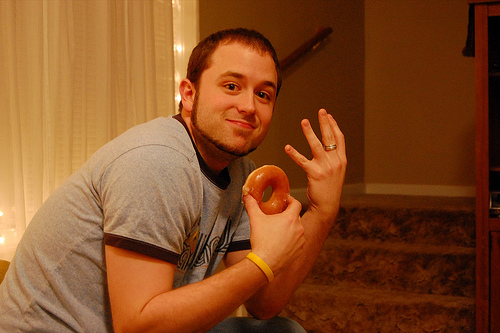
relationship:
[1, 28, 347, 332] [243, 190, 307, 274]
man has hand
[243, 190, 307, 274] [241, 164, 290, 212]
hand holding donut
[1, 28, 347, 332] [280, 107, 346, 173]
man holding up fingers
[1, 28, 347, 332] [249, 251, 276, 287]
man has wrist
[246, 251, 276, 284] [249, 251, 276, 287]
band around wrist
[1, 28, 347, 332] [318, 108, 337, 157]
man has finger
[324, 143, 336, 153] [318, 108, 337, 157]
ring around finger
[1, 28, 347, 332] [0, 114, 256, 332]
man wearing shirt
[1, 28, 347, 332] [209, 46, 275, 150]
man has face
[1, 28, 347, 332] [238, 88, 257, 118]
man has nose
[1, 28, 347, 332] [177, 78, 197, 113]
man has ear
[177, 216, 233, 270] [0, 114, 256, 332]
writing on front of shirt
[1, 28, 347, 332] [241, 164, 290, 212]
man holding donut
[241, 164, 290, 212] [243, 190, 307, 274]
donut held in hand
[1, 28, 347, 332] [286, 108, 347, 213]
man has hand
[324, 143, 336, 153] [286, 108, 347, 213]
ring worn on hand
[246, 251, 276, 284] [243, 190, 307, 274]
band below hand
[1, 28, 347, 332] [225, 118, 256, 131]
man has mouth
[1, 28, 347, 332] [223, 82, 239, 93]
man has eye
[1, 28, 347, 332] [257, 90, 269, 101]
man has eye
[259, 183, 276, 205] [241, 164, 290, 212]
hole in middle of donut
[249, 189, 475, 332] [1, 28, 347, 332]
staircase behind man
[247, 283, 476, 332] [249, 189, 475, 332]
stair part of staircase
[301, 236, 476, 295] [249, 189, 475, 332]
stair part of staircase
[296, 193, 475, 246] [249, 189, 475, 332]
stair part of staircase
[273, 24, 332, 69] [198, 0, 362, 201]
railing mounted on wall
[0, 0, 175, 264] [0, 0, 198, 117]
curtain covering window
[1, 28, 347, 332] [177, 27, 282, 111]
man has hair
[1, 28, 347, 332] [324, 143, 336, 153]
man wearing ring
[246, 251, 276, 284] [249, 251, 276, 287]
band around mans wrist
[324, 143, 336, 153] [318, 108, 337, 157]
ring around mans finger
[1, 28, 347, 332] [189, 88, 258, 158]
man has beard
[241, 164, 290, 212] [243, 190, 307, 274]
donut in mans hand